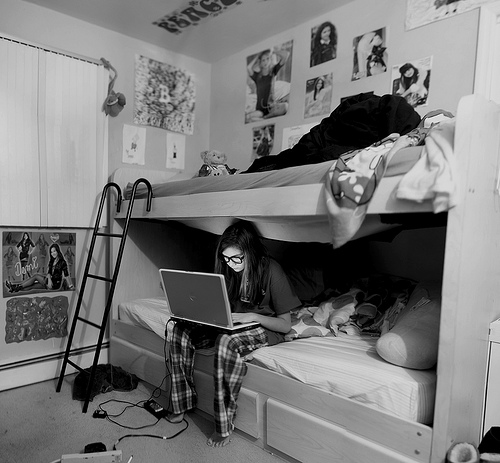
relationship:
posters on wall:
[247, 47, 376, 108] [204, 2, 495, 182]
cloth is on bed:
[241, 93, 423, 175] [116, 85, 496, 247]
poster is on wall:
[388, 58, 434, 109] [175, 7, 476, 160]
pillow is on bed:
[374, 298, 439, 370] [108, 92, 497, 462]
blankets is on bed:
[161, 109, 465, 239] [88, 130, 398, 259]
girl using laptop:
[167, 221, 293, 448] [152, 265, 262, 335]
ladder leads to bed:
[18, 184, 149, 316] [109, 93, 500, 229]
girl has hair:
[167, 215, 278, 461] [177, 207, 298, 293]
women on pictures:
[13, 230, 72, 284] [2, 231, 78, 298]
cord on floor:
[99, 373, 189, 450] [0, 373, 299, 459]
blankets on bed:
[325, 109, 459, 250] [137, 138, 464, 228]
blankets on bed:
[284, 284, 420, 337] [111, 295, 433, 460]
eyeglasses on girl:
[218, 250, 254, 265] [167, 221, 293, 448]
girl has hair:
[167, 221, 293, 448] [215, 218, 267, 309]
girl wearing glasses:
[167, 221, 293, 448] [215, 249, 245, 264]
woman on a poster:
[246, 47, 291, 120] [230, 36, 325, 148]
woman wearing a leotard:
[246, 47, 291, 120] [246, 63, 284, 119]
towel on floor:
[67, 357, 134, 400] [12, 391, 232, 458]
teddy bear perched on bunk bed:
[199, 143, 234, 183] [127, 92, 497, 456]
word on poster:
[156, 1, 242, 32] [149, 0, 256, 37]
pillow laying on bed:
[376, 281, 442, 369] [119, 281, 436, 402]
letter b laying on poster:
[155, 82, 170, 102] [130, 54, 196, 136]